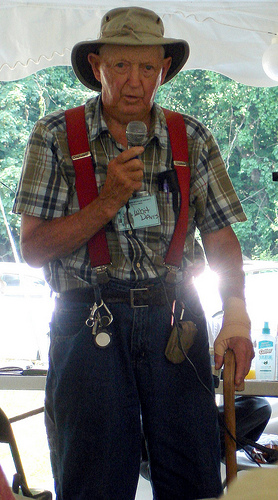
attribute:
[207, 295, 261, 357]
bandage on hand — brown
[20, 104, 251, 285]
short sleeved shirt — plaid, short sleeved, green, white, black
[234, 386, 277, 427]
knee of man — seated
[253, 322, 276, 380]
squeeze bottle — blue, white, red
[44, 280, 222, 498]
jeans — blue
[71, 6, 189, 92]
hat — frumpy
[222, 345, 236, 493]
cane — wooden, brown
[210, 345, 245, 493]
cane — brown, wooden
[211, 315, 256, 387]
hand — bandaged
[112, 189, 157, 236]
tag — covered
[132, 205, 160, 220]
writing — black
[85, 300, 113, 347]
keys — silver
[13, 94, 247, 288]
shirt — brown, plaid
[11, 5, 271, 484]
man — old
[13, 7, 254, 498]
man — old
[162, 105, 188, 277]
suspenders — red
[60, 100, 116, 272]
suspenders — red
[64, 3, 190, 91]
hat — tan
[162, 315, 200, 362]
case — brown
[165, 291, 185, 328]
hook — silver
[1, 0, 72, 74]
tent — white